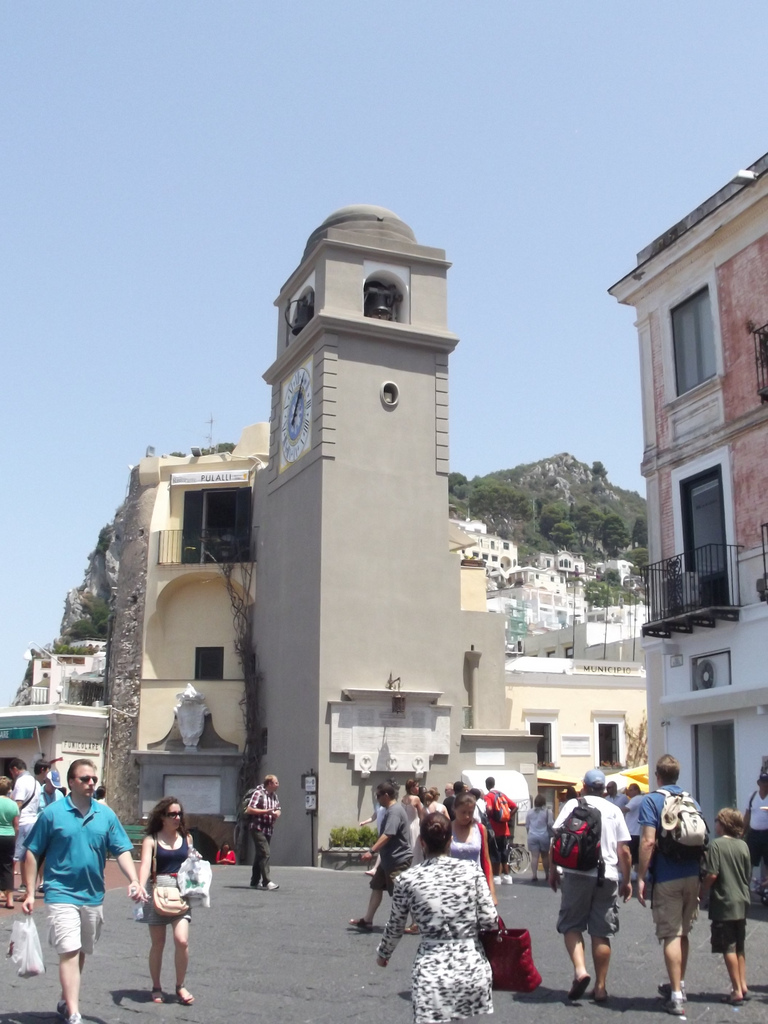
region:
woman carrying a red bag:
[367, 802, 553, 1019]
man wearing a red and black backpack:
[552, 761, 638, 994]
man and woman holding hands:
[17, 746, 225, 1021]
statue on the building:
[167, 676, 219, 754]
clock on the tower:
[272, 364, 334, 470]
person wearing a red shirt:
[213, 836, 233, 868]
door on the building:
[674, 460, 734, 564]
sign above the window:
[165, 470, 257, 485]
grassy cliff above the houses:
[517, 443, 615, 541]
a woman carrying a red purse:
[479, 926, 541, 991]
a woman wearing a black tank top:
[152, 832, 189, 871]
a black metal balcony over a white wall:
[639, 546, 739, 638]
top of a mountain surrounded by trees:
[449, 451, 645, 564]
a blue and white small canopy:
[1, 720, 54, 756]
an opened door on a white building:
[695, 718, 733, 838]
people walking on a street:
[3, 755, 766, 1022]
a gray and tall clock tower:
[251, 203, 541, 860]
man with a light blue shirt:
[14, 754, 150, 1022]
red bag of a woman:
[478, 912, 547, 1003]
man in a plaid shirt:
[241, 770, 290, 900]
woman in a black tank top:
[131, 789, 225, 1016]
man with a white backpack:
[629, 749, 722, 1022]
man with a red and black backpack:
[541, 765, 647, 1011]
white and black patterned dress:
[366, 848, 506, 1022]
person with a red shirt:
[474, 770, 523, 899]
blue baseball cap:
[579, 766, 607, 793]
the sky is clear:
[494, 136, 576, 211]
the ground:
[261, 928, 334, 990]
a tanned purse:
[153, 888, 190, 914]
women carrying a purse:
[492, 933, 542, 982]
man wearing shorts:
[563, 883, 615, 926]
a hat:
[580, 764, 610, 788]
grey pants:
[252, 829, 286, 877]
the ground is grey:
[274, 931, 332, 995]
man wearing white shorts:
[48, 905, 96, 943]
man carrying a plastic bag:
[9, 923, 59, 976]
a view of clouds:
[173, 306, 259, 367]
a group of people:
[31, 796, 703, 971]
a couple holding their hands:
[37, 770, 282, 990]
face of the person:
[60, 761, 112, 792]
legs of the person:
[8, 882, 286, 993]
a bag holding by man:
[17, 909, 64, 992]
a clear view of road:
[230, 881, 391, 1003]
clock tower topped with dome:
[262, 203, 458, 864]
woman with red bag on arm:
[377, 813, 540, 1021]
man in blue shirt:
[19, 758, 139, 1021]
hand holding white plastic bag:
[9, 901, 44, 978]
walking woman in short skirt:
[134, 796, 209, 1005]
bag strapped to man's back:
[641, 785, 707, 880]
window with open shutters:
[181, 484, 255, 560]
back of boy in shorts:
[703, 808, 753, 1004]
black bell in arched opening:
[362, 270, 410, 320]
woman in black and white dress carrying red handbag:
[371, 809, 548, 1021]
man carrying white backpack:
[635, 751, 709, 1018]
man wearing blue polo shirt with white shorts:
[8, 758, 137, 1022]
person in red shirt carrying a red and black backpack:
[479, 773, 519, 888]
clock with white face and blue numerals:
[273, 350, 317, 475]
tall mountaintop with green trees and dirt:
[443, 447, 645, 607]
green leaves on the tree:
[505, 516, 535, 542]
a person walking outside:
[402, 838, 508, 1013]